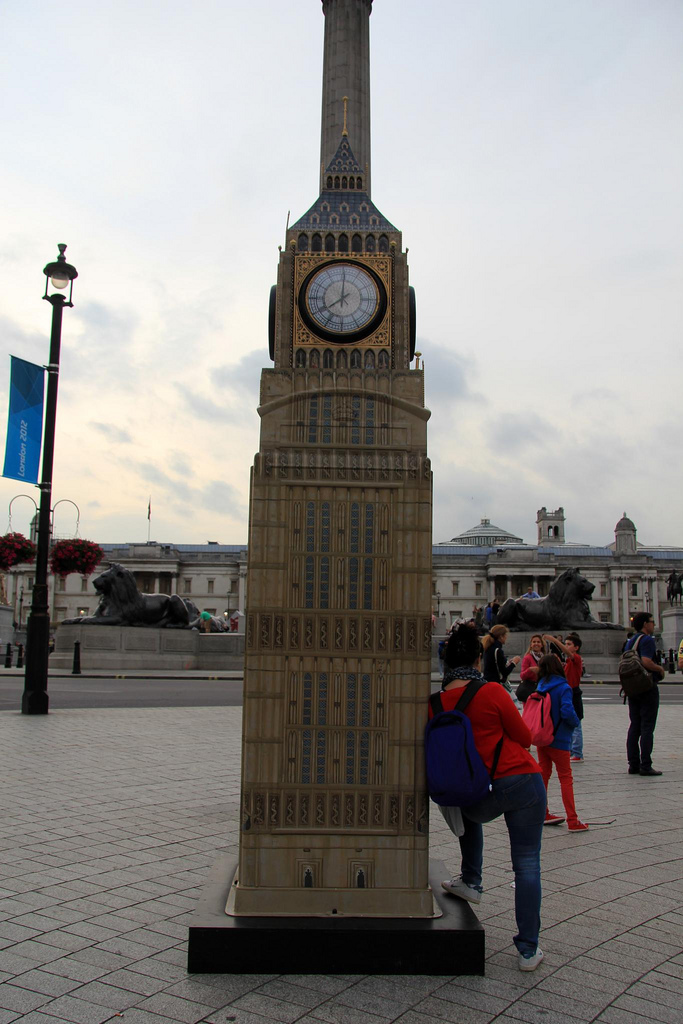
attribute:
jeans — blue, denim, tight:
[459, 771, 552, 956]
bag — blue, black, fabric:
[422, 689, 495, 808]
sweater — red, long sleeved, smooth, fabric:
[433, 681, 555, 781]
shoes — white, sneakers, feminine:
[436, 871, 545, 972]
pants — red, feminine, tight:
[536, 738, 586, 826]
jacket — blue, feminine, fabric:
[546, 680, 578, 747]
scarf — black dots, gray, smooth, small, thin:
[443, 664, 487, 682]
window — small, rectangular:
[55, 572, 67, 595]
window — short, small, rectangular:
[76, 573, 93, 592]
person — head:
[447, 622, 547, 963]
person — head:
[440, 623, 567, 980]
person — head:
[435, 618, 566, 960]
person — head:
[430, 615, 557, 981]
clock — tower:
[289, 250, 402, 345]